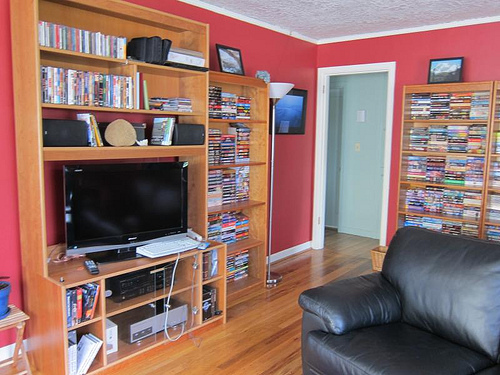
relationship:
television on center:
[56, 157, 194, 265] [7, 0, 231, 374]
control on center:
[81, 260, 99, 280] [7, 0, 231, 374]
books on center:
[34, 16, 207, 115] [7, 0, 231, 374]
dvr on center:
[113, 261, 191, 295] [7, 0, 231, 374]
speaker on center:
[41, 113, 91, 152] [7, 0, 231, 374]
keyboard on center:
[131, 234, 204, 265] [7, 0, 231, 374]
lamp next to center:
[260, 72, 298, 301] [7, 0, 231, 374]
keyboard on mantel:
[131, 234, 204, 265] [0, 0, 286, 373]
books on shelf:
[34, 16, 207, 115] [17, 20, 230, 160]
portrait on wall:
[270, 82, 308, 136] [0, 0, 500, 350]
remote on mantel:
[76, 254, 112, 283] [0, 0, 286, 373]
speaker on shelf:
[41, 113, 91, 152] [17, 20, 230, 160]